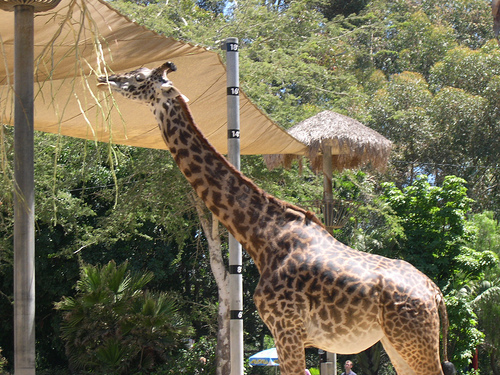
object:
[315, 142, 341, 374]
pole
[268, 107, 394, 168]
straw umbrella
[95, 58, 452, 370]
giraffe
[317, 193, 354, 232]
food basket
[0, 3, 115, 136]
giraffe feeder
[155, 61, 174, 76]
horns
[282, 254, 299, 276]
spot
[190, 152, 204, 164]
spot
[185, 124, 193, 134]
spot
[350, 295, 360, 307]
spot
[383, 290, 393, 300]
spot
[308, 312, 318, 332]
spot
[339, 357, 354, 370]
head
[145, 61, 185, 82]
ear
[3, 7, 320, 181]
canopy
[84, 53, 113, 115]
leaves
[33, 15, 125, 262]
tree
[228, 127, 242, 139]
number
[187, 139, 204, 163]
brown spot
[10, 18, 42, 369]
pole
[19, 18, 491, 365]
enclosure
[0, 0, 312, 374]
shed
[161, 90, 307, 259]
neck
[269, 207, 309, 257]
brown spot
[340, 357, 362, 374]
man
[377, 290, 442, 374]
legs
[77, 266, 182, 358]
palm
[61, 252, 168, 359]
trees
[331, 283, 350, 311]
spot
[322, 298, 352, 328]
spot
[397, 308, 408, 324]
spot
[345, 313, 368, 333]
spot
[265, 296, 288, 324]
spot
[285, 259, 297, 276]
spot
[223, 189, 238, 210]
spot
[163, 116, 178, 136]
spot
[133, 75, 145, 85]
giraffeeye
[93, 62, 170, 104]
head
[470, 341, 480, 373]
pole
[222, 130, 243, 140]
strip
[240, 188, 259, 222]
spot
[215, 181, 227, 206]
spot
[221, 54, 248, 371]
pole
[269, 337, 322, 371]
leg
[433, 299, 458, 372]
tail